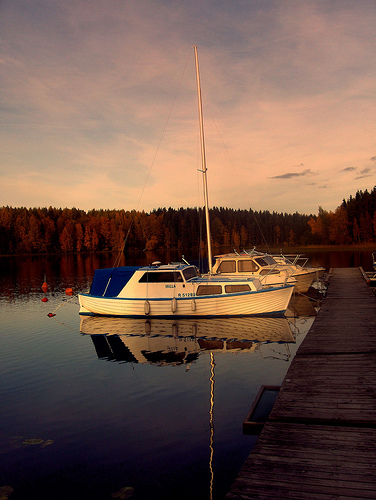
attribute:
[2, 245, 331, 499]
water — shallow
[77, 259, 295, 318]
boat — moored, safe, floating, blue, white, loaded, docked, registered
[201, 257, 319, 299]
boat — moored, safe, white, docked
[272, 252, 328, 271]
boat — moored, safe, docked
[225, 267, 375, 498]
dock — wooden, long, old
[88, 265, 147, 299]
tarp — blue, dark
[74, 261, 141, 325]
end — blue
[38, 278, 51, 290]
buoy — strung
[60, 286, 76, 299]
buoy — strung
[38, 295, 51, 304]
buoy — strung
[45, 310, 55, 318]
buoy — strung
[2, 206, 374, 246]
foliage — fall, pine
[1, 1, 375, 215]
sky — hazy, blue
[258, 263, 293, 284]
equipment — ready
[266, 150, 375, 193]
clouds — dark, approaching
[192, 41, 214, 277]
mast — tall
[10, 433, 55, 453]
pads — floating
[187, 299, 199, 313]
float — white, hanging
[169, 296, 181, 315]
float — white, hanging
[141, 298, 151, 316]
float — white, hanging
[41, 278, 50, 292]
buoy — red, floating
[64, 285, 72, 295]
buoy — red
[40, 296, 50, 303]
buoy — red, floating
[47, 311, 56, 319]
buoy — red, floating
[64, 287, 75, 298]
buoy — floating